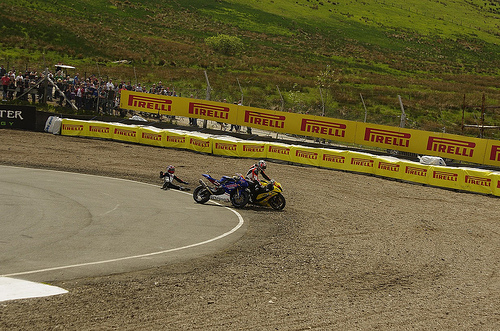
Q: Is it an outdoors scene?
A: Yes, it is outdoors.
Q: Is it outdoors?
A: Yes, it is outdoors.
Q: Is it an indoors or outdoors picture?
A: It is outdoors.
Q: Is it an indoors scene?
A: No, it is outdoors.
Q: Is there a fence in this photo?
A: Yes, there is a fence.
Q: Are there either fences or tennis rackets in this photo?
A: Yes, there is a fence.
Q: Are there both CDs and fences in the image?
A: No, there is a fence but no cds.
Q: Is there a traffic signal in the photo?
A: No, there are no traffic lights.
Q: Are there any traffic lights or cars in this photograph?
A: No, there are no traffic lights or cars.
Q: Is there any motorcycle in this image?
A: Yes, there is a motorcycle.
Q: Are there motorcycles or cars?
A: Yes, there is a motorcycle.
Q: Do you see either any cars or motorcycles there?
A: Yes, there is a motorcycle.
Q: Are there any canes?
A: No, there are no canes.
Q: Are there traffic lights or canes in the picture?
A: No, there are no canes or traffic lights.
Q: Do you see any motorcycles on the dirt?
A: Yes, there is a motorcycle on the dirt.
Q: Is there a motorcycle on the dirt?
A: Yes, there is a motorcycle on the dirt.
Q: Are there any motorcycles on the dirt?
A: Yes, there is a motorcycle on the dirt.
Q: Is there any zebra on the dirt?
A: No, there is a motorcycle on the dirt.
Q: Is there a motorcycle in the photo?
A: Yes, there is a motorcycle.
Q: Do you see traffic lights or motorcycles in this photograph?
A: Yes, there is a motorcycle.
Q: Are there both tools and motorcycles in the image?
A: No, there is a motorcycle but no tools.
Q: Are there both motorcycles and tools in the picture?
A: No, there is a motorcycle but no tools.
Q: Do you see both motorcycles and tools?
A: No, there is a motorcycle but no tools.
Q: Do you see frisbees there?
A: No, there are no frisbees.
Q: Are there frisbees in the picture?
A: No, there are no frisbees.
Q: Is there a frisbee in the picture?
A: No, there are no frisbees.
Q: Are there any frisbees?
A: No, there are no frisbees.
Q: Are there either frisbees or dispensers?
A: No, there are no frisbees or dispensers.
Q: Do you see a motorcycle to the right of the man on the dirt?
A: Yes, there is a motorcycle to the right of the man.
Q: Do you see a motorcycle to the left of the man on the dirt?
A: No, the motorcycle is to the right of the man.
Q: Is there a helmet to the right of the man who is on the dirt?
A: No, there is a motorcycle to the right of the man.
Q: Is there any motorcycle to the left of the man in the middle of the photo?
A: Yes, there is a motorcycle to the left of the man.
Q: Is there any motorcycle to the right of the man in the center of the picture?
A: No, the motorcycle is to the left of the man.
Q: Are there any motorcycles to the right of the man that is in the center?
A: No, the motorcycle is to the left of the man.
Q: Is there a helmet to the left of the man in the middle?
A: No, there is a motorcycle to the left of the man.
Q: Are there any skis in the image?
A: No, there are no skis.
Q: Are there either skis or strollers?
A: No, there are no skis or strollers.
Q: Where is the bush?
A: The bush is on the hillside.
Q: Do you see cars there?
A: No, there are no cars.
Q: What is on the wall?
A: The sign is on the wall.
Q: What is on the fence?
A: The sign is on the fence.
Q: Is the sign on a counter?
A: No, the sign is on the fence.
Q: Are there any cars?
A: No, there are no cars.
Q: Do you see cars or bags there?
A: No, there are no cars or bags.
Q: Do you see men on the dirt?
A: Yes, there is a man on the dirt.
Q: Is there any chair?
A: No, there are no chairs.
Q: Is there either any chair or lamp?
A: No, there are no chairs or lamps.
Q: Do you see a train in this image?
A: No, there are no trains.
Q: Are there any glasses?
A: No, there are no glasses.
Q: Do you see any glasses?
A: No, there are no glasses.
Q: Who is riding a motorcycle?
A: The man is riding a motorcycle.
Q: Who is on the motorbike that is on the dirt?
A: The man is on the motorbike.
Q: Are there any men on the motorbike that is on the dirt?
A: Yes, there is a man on the motorcycle.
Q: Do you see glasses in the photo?
A: No, there are no glasses.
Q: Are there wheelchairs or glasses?
A: No, there are no glasses or wheelchairs.